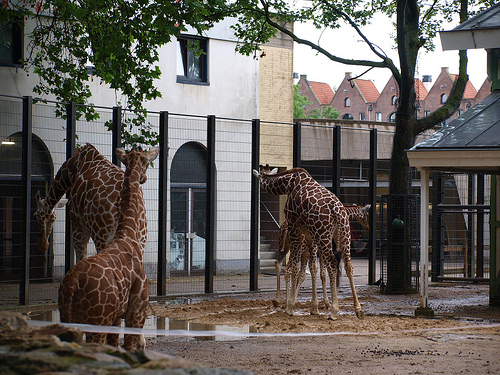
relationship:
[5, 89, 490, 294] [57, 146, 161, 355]
fence enclosing giraffe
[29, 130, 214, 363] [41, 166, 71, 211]
giraffe bending neck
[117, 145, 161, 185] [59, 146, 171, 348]
head on giraffe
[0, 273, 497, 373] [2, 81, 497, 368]
dirt terrain in enclosure